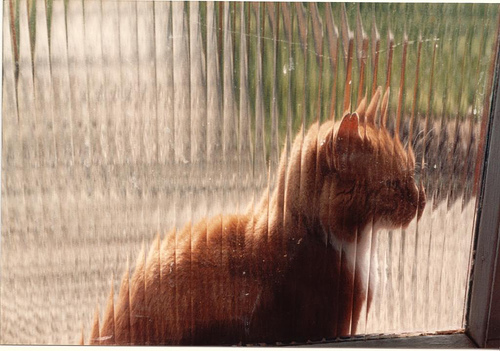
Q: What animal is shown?
A: A cat.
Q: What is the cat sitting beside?
A: A window.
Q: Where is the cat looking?
A: To the right.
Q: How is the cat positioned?
A: Sitting.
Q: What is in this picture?
A: A cat.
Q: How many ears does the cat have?
A: Two.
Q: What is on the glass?
A: Lines.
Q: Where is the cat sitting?
A: Behind door.